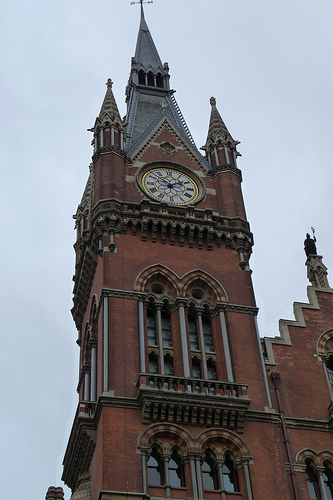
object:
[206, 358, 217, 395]
window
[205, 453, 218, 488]
reflection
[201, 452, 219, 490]
window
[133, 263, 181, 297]
arches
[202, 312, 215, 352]
windows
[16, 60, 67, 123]
clouds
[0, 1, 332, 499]
blue sky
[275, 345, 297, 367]
chipping paint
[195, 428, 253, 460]
awning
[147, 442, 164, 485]
window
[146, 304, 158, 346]
window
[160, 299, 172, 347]
window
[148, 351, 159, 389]
window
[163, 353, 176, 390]
window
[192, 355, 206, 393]
window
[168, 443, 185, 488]
window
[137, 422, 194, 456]
arch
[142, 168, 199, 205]
clock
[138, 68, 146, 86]
opening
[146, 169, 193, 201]
face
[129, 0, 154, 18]
cross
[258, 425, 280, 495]
bricks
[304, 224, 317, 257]
statue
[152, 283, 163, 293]
window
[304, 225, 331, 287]
roof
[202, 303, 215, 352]
window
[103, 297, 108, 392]
column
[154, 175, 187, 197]
circle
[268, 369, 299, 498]
pipe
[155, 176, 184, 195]
dials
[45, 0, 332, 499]
building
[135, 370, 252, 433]
balcony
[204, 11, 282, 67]
clouds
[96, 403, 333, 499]
wall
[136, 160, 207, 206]
accents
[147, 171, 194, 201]
numerals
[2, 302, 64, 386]
clouds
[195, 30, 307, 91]
clouds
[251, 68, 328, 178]
clouds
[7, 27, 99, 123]
clouds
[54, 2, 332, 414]
roof top